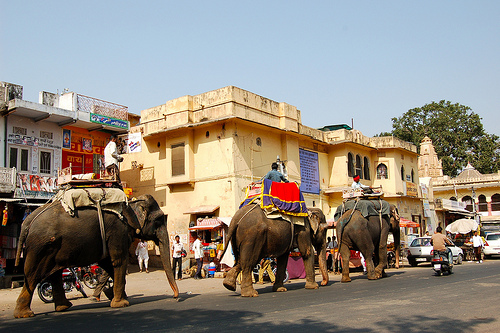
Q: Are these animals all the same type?
A: Yes, all the animals are elephants.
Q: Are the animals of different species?
A: No, all the animals are elephants.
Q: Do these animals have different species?
A: No, all the animals are elephants.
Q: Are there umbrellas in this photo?
A: Yes, there is an umbrella.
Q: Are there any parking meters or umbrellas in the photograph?
A: Yes, there is an umbrella.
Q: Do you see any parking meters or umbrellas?
A: Yes, there is an umbrella.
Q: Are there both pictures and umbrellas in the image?
A: No, there is an umbrella but no pictures.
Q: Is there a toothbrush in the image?
A: No, there are no toothbrushes.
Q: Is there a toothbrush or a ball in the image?
A: No, there are no toothbrushes or balls.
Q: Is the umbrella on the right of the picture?
A: Yes, the umbrella is on the right of the image.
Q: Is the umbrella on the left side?
A: No, the umbrella is on the right of the image.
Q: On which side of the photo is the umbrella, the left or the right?
A: The umbrella is on the right of the image.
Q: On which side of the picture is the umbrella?
A: The umbrella is on the right of the image.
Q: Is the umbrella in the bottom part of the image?
A: Yes, the umbrella is in the bottom of the image.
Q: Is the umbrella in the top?
A: No, the umbrella is in the bottom of the image.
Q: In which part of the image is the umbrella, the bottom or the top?
A: The umbrella is in the bottom of the image.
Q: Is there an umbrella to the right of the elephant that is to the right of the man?
A: Yes, there is an umbrella to the right of the elephant.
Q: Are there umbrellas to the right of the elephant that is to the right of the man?
A: Yes, there is an umbrella to the right of the elephant.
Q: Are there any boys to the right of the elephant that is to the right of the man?
A: No, there is an umbrella to the right of the elephant.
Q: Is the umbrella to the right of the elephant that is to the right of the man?
A: Yes, the umbrella is to the right of the elephant.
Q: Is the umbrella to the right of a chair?
A: No, the umbrella is to the right of the elephant.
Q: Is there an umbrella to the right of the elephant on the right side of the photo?
A: Yes, there is an umbrella to the right of the elephant.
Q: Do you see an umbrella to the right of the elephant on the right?
A: Yes, there is an umbrella to the right of the elephant.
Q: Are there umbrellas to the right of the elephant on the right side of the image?
A: Yes, there is an umbrella to the right of the elephant.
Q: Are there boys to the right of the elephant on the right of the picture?
A: No, there is an umbrella to the right of the elephant.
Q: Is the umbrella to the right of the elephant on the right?
A: Yes, the umbrella is to the right of the elephant.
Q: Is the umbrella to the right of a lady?
A: No, the umbrella is to the right of the elephant.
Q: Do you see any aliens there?
A: No, there are no aliens.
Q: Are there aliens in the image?
A: No, there are no aliens.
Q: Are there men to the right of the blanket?
A: Yes, there is a man to the right of the blanket.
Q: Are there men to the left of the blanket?
A: No, the man is to the right of the blanket.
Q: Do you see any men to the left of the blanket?
A: No, the man is to the right of the blanket.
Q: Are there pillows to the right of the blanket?
A: No, there is a man to the right of the blanket.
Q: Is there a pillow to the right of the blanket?
A: No, there is a man to the right of the blanket.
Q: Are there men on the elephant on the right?
A: Yes, there is a man on the elephant.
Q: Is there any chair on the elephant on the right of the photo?
A: No, there is a man on the elephant.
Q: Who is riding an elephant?
A: The man is riding an elephant.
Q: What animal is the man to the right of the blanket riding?
A: The man is riding an elephant.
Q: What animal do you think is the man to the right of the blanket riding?
A: The man is riding an elephant.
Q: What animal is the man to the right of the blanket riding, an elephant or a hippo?
A: The man is riding an elephant.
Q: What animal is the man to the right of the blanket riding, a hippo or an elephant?
A: The man is riding an elephant.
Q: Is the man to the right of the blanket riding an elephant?
A: Yes, the man is riding an elephant.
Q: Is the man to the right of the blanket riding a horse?
A: No, the man is riding an elephant.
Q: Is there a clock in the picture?
A: No, there are no clocks.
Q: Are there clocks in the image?
A: No, there are no clocks.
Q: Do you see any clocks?
A: No, there are no clocks.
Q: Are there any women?
A: No, there are no women.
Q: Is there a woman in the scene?
A: No, there are no women.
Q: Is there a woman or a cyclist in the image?
A: No, there are no women or cyclists.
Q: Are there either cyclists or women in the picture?
A: No, there are no women or cyclists.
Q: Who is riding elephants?
A: The man is riding elephants.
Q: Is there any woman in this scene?
A: No, there are no women.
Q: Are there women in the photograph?
A: No, there are no women.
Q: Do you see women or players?
A: No, there are no women or players.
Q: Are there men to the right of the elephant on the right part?
A: Yes, there is a man to the right of the elephant.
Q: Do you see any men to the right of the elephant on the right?
A: Yes, there is a man to the right of the elephant.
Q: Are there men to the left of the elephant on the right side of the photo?
A: No, the man is to the right of the elephant.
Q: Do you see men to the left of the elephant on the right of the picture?
A: No, the man is to the right of the elephant.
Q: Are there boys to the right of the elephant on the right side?
A: No, there is a man to the right of the elephant.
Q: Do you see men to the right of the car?
A: Yes, there is a man to the right of the car.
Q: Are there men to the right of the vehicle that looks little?
A: Yes, there is a man to the right of the car.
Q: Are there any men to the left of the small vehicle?
A: No, the man is to the right of the car.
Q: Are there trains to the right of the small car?
A: No, there is a man to the right of the car.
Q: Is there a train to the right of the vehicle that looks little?
A: No, there is a man to the right of the car.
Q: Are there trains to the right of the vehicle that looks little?
A: No, there is a man to the right of the car.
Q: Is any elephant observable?
A: Yes, there is an elephant.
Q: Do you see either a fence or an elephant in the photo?
A: Yes, there is an elephant.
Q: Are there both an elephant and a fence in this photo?
A: Yes, there are both an elephant and a fence.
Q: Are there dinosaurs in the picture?
A: No, there are no dinosaurs.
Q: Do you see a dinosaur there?
A: No, there are no dinosaurs.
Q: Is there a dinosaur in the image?
A: No, there are no dinosaurs.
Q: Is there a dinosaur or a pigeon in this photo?
A: No, there are no dinosaurs or pigeons.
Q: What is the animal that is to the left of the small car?
A: The animal is an elephant.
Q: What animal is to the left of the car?
A: The animal is an elephant.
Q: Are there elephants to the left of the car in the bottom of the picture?
A: Yes, there is an elephant to the left of the car.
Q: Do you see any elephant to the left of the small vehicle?
A: Yes, there is an elephant to the left of the car.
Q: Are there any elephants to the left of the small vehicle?
A: Yes, there is an elephant to the left of the car.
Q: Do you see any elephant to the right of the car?
A: No, the elephant is to the left of the car.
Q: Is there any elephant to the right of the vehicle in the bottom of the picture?
A: No, the elephant is to the left of the car.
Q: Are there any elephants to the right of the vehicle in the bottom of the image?
A: No, the elephant is to the left of the car.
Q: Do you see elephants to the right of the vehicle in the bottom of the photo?
A: No, the elephant is to the left of the car.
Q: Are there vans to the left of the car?
A: No, there is an elephant to the left of the car.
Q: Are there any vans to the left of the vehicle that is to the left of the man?
A: No, there is an elephant to the left of the car.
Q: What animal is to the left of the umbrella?
A: The animal is an elephant.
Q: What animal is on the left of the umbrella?
A: The animal is an elephant.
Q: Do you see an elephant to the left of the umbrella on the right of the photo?
A: Yes, there is an elephant to the left of the umbrella.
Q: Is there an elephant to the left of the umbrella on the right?
A: Yes, there is an elephant to the left of the umbrella.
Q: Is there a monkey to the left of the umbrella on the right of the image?
A: No, there is an elephant to the left of the umbrella.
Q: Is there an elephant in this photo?
A: Yes, there is an elephant.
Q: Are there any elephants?
A: Yes, there is an elephant.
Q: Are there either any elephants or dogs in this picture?
A: Yes, there is an elephant.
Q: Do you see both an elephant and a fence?
A: Yes, there are both an elephant and a fence.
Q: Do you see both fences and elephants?
A: Yes, there are both an elephant and a fence.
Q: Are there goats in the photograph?
A: No, there are no goats.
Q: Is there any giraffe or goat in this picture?
A: No, there are no goats or giraffes.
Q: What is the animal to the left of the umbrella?
A: The animal is an elephant.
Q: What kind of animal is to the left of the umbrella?
A: The animal is an elephant.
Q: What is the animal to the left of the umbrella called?
A: The animal is an elephant.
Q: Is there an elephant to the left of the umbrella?
A: Yes, there is an elephant to the left of the umbrella.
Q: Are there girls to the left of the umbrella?
A: No, there is an elephant to the left of the umbrella.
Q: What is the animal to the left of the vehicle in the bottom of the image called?
A: The animal is an elephant.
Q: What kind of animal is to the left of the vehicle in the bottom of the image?
A: The animal is an elephant.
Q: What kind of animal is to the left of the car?
A: The animal is an elephant.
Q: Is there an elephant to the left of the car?
A: Yes, there is an elephant to the left of the car.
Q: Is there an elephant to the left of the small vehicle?
A: Yes, there is an elephant to the left of the car.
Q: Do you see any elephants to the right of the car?
A: No, the elephant is to the left of the car.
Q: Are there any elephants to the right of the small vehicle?
A: No, the elephant is to the left of the car.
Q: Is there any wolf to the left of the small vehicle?
A: No, there is an elephant to the left of the car.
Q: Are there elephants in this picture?
A: Yes, there are elephants.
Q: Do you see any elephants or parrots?
A: Yes, there are elephants.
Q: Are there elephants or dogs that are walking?
A: Yes, the elephants are walking.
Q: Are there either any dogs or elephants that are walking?
A: Yes, the elephants are walking.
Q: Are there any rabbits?
A: No, there are no rabbits.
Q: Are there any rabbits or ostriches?
A: No, there are no rabbits or ostriches.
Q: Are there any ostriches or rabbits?
A: No, there are no rabbits or ostriches.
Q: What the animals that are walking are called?
A: The animals are elephants.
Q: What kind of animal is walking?
A: The animal is elephants.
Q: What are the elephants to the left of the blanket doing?
A: The elephants are walking.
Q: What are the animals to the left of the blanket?
A: The animals are elephants.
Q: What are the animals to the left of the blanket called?
A: The animals are elephants.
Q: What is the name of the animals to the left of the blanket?
A: The animals are elephants.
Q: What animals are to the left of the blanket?
A: The animals are elephants.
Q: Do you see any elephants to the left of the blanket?
A: Yes, there are elephants to the left of the blanket.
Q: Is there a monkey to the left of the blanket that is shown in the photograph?
A: No, there are elephants to the left of the blanket.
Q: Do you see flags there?
A: No, there are no flags.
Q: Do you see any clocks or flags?
A: No, there are no flags or clocks.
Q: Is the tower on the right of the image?
A: Yes, the tower is on the right of the image.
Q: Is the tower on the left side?
A: No, the tower is on the right of the image.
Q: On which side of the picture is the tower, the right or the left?
A: The tower is on the right of the image.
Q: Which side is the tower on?
A: The tower is on the right of the image.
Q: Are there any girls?
A: No, there are no girls.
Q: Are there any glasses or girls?
A: No, there are no girls or glasses.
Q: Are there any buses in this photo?
A: No, there are no buses.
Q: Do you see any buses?
A: No, there are no buses.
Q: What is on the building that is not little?
A: The sign is on the building.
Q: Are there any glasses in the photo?
A: No, there are no glasses.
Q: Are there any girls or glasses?
A: No, there are no glasses or girls.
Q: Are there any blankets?
A: Yes, there is a blanket.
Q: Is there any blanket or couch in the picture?
A: Yes, there is a blanket.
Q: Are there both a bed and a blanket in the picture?
A: No, there is a blanket but no beds.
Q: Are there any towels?
A: No, there are no towels.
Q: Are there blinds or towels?
A: No, there are no towels or blinds.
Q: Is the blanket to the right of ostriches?
A: No, the blanket is to the right of the elephants.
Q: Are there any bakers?
A: No, there are no bakers.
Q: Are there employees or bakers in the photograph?
A: No, there are no bakers or employees.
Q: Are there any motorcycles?
A: Yes, there is a motorcycle.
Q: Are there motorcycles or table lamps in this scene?
A: Yes, there is a motorcycle.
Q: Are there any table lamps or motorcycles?
A: Yes, there is a motorcycle.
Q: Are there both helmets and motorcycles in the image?
A: No, there is a motorcycle but no helmets.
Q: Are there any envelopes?
A: No, there are no envelopes.